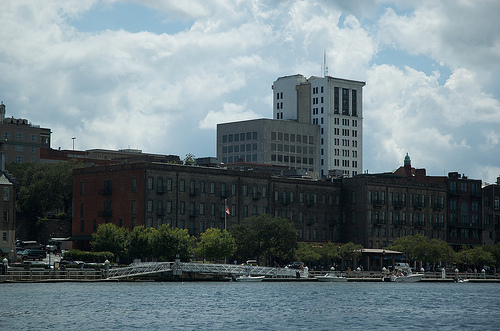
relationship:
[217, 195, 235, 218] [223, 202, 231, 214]
flag of flag